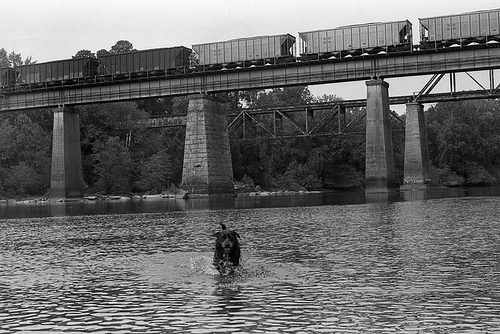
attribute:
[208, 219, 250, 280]
dog — swimming, dark, wet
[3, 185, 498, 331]
water — extensive, calm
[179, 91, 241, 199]
pillar — stack stoned, concrete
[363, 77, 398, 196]
pillar — concrete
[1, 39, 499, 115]
bridge — high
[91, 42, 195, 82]
car — black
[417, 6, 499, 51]
car — silver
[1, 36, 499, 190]
vegetation — thick